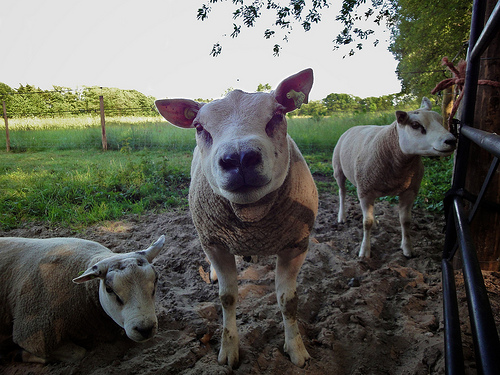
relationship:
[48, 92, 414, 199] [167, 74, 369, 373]
field behind sheep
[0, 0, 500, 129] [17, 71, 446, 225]
trees behind sheep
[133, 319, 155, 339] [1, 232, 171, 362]
nose on sheep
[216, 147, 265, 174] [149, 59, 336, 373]
nose of middle sheep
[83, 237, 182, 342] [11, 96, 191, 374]
head of sheep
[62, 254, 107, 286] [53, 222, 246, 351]
ear of sheep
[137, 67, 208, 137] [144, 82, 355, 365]
ear of sheep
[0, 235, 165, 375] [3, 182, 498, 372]
animal on sand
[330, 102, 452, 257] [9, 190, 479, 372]
animal standing in mud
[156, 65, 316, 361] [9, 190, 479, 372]
animal standing in mud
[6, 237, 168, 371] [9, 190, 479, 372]
animal standing in mud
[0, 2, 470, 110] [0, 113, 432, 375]
trees around field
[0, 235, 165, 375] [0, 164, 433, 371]
animal resting in shade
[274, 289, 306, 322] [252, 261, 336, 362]
mud on leg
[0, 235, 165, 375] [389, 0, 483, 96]
animal in shade from tree